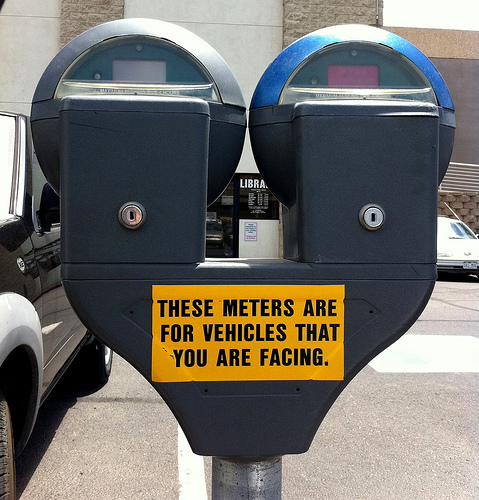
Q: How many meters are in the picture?
A: Two.